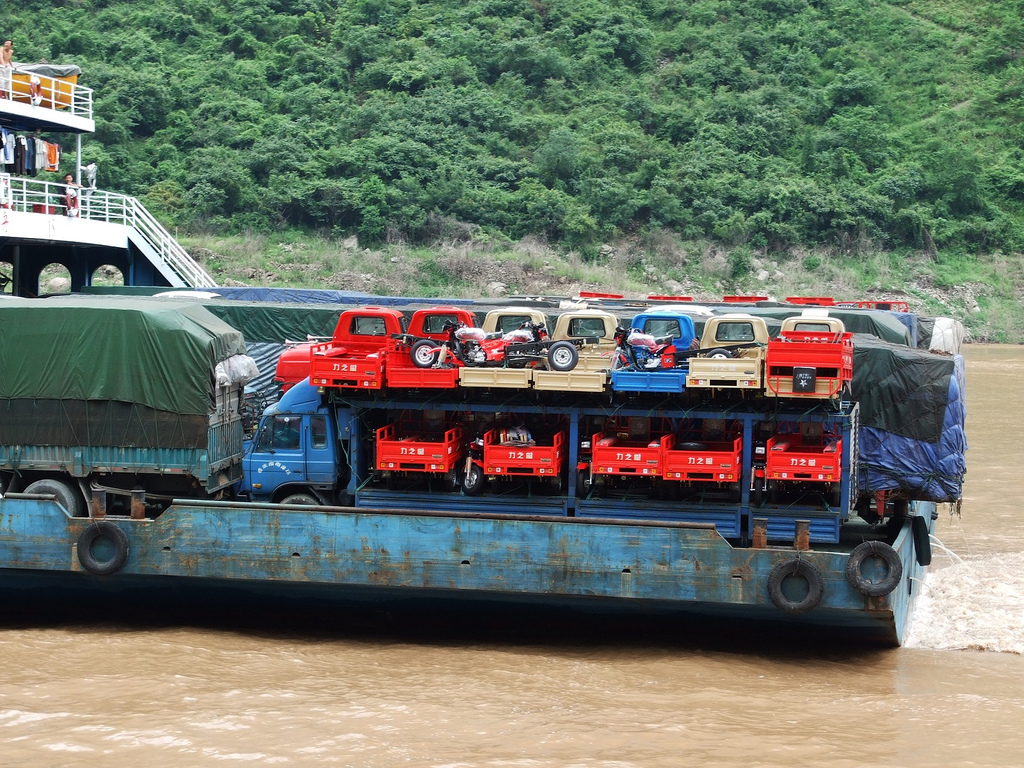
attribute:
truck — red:
[288, 294, 412, 394]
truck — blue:
[233, 307, 870, 542]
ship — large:
[13, 44, 982, 690]